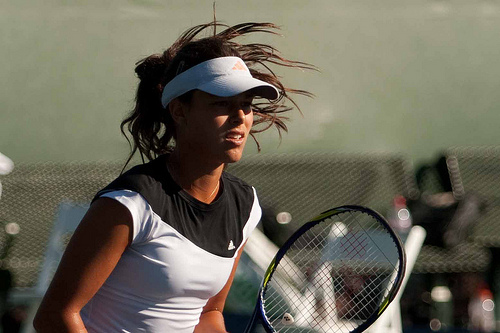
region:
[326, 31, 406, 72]
this is the wall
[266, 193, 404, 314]
this is a racket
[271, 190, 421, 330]
the racket is big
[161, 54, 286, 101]
this is a cap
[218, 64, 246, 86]
the cap is white in color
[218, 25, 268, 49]
this is the hair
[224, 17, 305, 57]
the hair is long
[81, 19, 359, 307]
this is a woman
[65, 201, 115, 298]
this is an arm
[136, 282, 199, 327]
the vest is white in color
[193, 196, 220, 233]
part of a collar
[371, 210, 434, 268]
edge fo a rackrt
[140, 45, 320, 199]
girl has brown hair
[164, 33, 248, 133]
girl has white cap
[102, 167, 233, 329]
black and white shirt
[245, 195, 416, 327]
girl has black racket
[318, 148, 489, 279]
fence is behind girl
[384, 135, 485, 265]
people sitting behind girl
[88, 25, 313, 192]
girl has long hair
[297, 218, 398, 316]
grey strings on racket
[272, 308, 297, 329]
small dampener on racket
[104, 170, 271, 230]
black stripe on shirt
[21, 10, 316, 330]
tennis player holding racket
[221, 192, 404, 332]
tennis racket in womans hands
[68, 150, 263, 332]
woman wearing black and white shirt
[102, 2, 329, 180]
womans hair is brown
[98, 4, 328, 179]
womans hair is wild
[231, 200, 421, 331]
tennis racket is purple and yellow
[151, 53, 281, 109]
woman wearing sun visor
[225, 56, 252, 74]
symbol on sun visor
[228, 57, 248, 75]
symbol on sun visor is orange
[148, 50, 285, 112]
womans sun visor is white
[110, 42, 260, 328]
this is a tennis player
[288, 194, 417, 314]
she is holding aracket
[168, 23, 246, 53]
this is the hair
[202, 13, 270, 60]
the hair is wavy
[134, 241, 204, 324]
this is a blouse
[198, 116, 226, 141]
the player is light skinned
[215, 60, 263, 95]
this is a cap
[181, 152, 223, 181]
this is the neck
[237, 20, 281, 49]
the hair is wavy